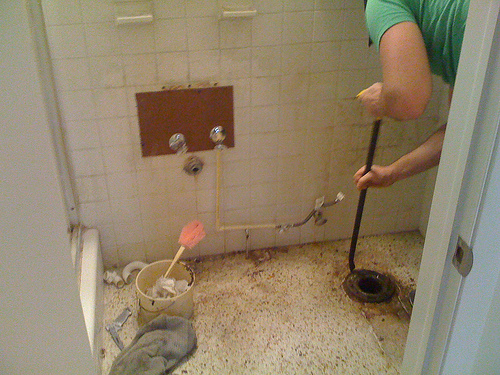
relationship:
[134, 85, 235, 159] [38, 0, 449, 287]
square on wall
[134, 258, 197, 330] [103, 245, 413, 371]
bucket on ground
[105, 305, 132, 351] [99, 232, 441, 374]
knife on floor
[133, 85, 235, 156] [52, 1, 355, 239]
square on wall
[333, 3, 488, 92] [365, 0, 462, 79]
man has shirt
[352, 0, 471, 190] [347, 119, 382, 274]
man holds metal pole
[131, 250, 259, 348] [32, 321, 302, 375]
bucket on floor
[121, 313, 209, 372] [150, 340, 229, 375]
towel on floor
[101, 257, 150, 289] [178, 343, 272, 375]
pipes on floor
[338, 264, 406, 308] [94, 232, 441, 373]
drain on floor